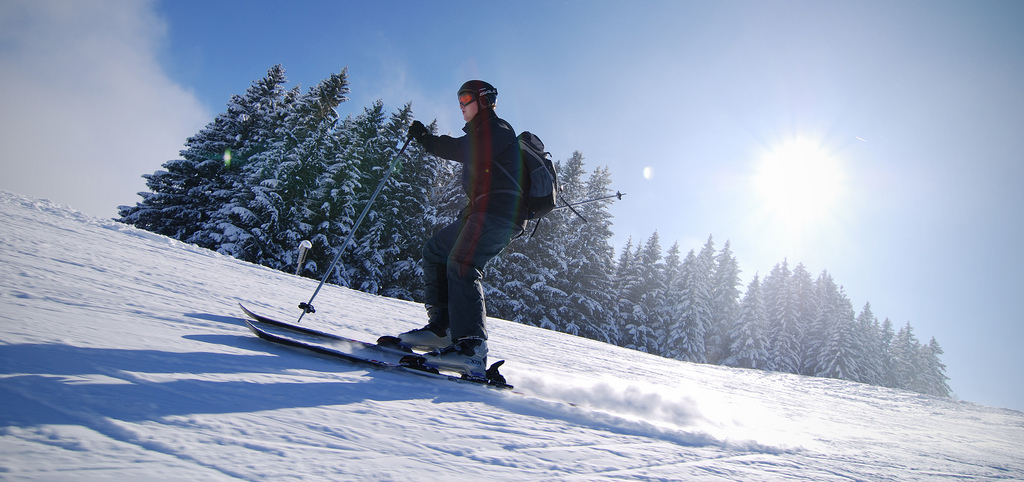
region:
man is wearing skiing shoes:
[255, 312, 527, 389]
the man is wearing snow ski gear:
[81, 9, 894, 463]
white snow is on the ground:
[0, 206, 738, 478]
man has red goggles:
[447, 92, 477, 108]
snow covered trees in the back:
[109, 67, 443, 284]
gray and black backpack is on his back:
[507, 132, 553, 215]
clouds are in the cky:
[4, 3, 227, 219]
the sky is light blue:
[196, 26, 513, 94]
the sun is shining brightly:
[702, 139, 877, 244]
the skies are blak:
[231, 282, 529, 404]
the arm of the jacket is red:
[462, 121, 497, 271]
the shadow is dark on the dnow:
[21, 319, 388, 457]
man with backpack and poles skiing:
[240, 74, 555, 398]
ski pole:
[274, 118, 415, 327]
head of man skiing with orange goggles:
[455, 74, 498, 131]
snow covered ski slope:
[0, 188, 1013, 477]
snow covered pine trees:
[104, 52, 956, 397]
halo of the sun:
[724, 128, 851, 236]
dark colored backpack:
[502, 127, 557, 227]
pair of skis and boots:
[230, 294, 513, 389]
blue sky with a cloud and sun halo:
[3, 9, 1016, 395]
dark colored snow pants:
[419, 200, 522, 381]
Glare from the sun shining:
[669, 80, 987, 248]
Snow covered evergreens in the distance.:
[131, 38, 903, 279]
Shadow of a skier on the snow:
[1, 308, 422, 438]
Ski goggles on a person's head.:
[450, 84, 499, 113]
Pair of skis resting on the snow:
[212, 289, 548, 385]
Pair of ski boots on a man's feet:
[378, 311, 487, 368]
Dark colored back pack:
[504, 118, 587, 239]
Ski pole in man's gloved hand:
[272, 114, 441, 340]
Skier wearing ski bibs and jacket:
[389, 59, 577, 367]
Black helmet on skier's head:
[453, 68, 521, 132]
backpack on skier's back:
[516, 125, 561, 225]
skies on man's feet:
[232, 293, 543, 401]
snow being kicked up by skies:
[503, 358, 830, 456]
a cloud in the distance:
[2, 1, 209, 243]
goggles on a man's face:
[454, 89, 493, 106]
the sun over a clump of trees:
[744, 124, 849, 260]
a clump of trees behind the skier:
[118, 56, 964, 402]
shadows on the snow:
[2, 329, 435, 432]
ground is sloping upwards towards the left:
[1, 195, 1020, 474]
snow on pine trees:
[231, 62, 327, 275]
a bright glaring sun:
[767, 118, 860, 258]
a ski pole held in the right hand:
[294, 130, 390, 318]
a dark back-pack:
[518, 118, 564, 224]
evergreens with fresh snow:
[228, 61, 328, 255]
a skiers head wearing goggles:
[443, 49, 505, 132]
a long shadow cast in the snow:
[53, 254, 234, 455]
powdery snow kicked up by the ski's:
[540, 336, 807, 453]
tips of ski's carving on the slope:
[223, 270, 291, 384]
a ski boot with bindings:
[385, 334, 516, 401]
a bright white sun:
[740, 115, 858, 242]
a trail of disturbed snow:
[537, 355, 845, 461]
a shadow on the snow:
[1, 338, 458, 425]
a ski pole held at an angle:
[288, 115, 412, 324]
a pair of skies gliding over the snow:
[234, 302, 535, 389]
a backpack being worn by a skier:
[512, 121, 570, 232]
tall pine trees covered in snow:
[113, 55, 409, 275]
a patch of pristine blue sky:
[197, 5, 315, 62]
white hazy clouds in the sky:
[0, 6, 163, 191]